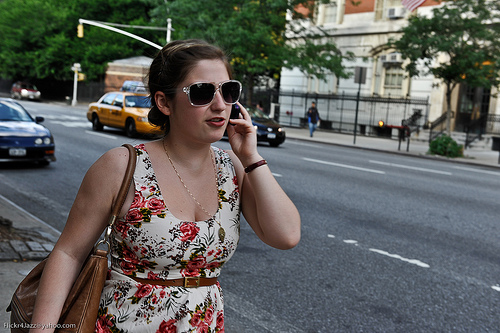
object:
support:
[86, 20, 176, 31]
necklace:
[162, 140, 223, 236]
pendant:
[218, 227, 226, 243]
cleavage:
[189, 209, 203, 223]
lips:
[205, 117, 226, 121]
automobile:
[0, 96, 58, 170]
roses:
[143, 196, 170, 216]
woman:
[24, 37, 306, 332]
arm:
[29, 145, 129, 333]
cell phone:
[229, 102, 241, 126]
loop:
[93, 241, 113, 256]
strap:
[109, 142, 138, 224]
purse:
[5, 142, 138, 332]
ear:
[153, 90, 171, 116]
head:
[147, 39, 242, 146]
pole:
[73, 22, 170, 32]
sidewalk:
[280, 121, 500, 168]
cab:
[83, 90, 166, 139]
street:
[0, 97, 497, 330]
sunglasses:
[161, 79, 244, 108]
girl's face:
[171, 62, 235, 142]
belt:
[123, 274, 220, 289]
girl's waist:
[105, 258, 229, 307]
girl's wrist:
[239, 153, 271, 173]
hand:
[228, 102, 259, 160]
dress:
[72, 141, 247, 332]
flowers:
[186, 256, 207, 271]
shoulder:
[86, 144, 155, 195]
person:
[306, 101, 323, 138]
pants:
[308, 117, 318, 136]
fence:
[242, 88, 430, 141]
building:
[274, 1, 500, 150]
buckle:
[184, 276, 201, 288]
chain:
[161, 138, 227, 242]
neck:
[171, 136, 208, 162]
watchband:
[244, 159, 268, 173]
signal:
[77, 24, 85, 37]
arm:
[80, 19, 163, 50]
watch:
[244, 159, 268, 174]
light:
[76, 24, 85, 38]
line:
[360, 245, 428, 274]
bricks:
[9, 239, 31, 252]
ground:
[232, 138, 500, 330]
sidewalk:
[0, 196, 67, 320]